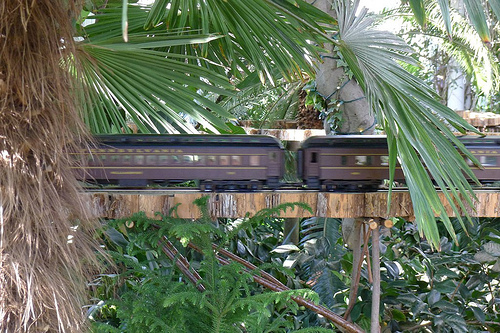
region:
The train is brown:
[58, 134, 498, 196]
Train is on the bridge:
[67, 131, 497, 328]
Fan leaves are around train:
[69, 0, 482, 252]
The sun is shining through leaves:
[70, 0, 498, 112]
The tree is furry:
[1, 0, 73, 332]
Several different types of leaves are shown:
[93, 212, 499, 330]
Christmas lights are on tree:
[296, 0, 380, 138]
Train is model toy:
[68, 133, 499, 194]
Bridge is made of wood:
[70, 185, 497, 331]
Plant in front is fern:
[95, 197, 322, 331]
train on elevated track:
[51, 102, 496, 281]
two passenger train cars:
[73, 119, 498, 206]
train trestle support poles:
[142, 207, 421, 329]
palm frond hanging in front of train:
[308, 6, 484, 263]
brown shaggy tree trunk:
[3, 7, 108, 324]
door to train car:
[302, 133, 330, 199]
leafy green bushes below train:
[113, 223, 494, 331]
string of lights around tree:
[295, 3, 385, 134]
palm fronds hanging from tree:
[76, 2, 330, 126]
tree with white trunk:
[421, 31, 490, 124]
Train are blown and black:
[65, 101, 497, 203]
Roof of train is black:
[96, 113, 496, 150]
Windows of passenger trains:
[66, 148, 264, 168]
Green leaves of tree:
[2, 5, 347, 330]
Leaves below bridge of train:
[113, 205, 485, 330]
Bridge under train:
[85, 176, 498, 307]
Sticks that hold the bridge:
[126, 221, 404, 331]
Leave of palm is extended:
[321, 1, 498, 258]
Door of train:
[301, 143, 323, 182]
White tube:
[436, 56, 471, 110]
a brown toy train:
[88, 129, 383, 187]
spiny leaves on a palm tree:
[126, 25, 238, 82]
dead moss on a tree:
[14, 114, 99, 314]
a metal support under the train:
[354, 222, 406, 330]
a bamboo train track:
[123, 194, 410, 222]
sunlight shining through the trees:
[364, 6, 424, 51]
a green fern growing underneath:
[161, 259, 272, 331]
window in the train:
[89, 146, 270, 173]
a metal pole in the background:
[449, 64, 469, 111]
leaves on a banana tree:
[415, 246, 472, 315]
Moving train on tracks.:
[9, 131, 498, 220]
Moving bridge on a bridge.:
[35, 130, 498, 288]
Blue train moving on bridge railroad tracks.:
[61, 131, 498, 251]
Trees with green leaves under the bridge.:
[87, 222, 498, 329]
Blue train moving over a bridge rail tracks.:
[57, 130, 499, 262]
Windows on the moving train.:
[83, 148, 268, 169]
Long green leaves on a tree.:
[88, 12, 487, 247]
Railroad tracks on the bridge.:
[58, 184, 498, 219]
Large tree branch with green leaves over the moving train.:
[62, 1, 499, 252]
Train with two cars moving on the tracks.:
[74, 132, 499, 193]